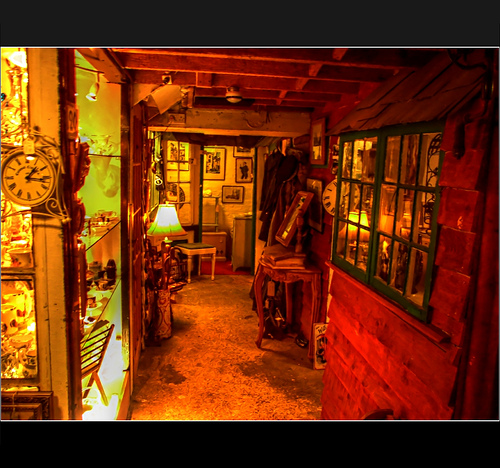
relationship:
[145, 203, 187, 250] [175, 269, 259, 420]
lamp on side of hallway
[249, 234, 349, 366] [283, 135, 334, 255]
table against wall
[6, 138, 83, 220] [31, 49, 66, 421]
clock on frame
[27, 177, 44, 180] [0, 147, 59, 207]
hand on clock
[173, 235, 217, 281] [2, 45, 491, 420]
chair in room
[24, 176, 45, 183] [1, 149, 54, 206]
hand on clock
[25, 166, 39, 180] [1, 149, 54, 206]
hand on clock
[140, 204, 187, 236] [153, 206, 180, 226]
shade on light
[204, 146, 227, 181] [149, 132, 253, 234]
picture on wall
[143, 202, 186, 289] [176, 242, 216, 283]
light near chair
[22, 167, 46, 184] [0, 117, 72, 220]
hands on clock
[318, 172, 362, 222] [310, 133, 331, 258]
round clock on wall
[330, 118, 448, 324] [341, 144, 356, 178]
window has pane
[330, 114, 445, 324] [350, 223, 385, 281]
window has pane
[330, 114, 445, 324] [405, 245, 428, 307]
window has pane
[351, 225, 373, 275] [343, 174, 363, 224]
window pane has pane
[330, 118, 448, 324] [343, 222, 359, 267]
window has pane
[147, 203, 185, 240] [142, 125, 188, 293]
lamp shade on corner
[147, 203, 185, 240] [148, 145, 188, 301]
lamp shade on corner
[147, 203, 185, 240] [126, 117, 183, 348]
lamp shade on corner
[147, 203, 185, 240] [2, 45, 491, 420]
lamp shade in room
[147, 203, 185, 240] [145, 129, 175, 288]
lamp shade on corner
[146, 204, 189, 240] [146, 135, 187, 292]
lamp on corner